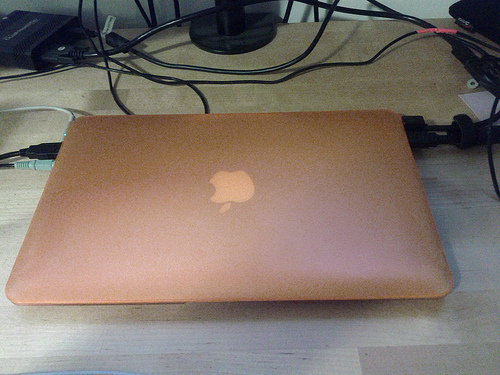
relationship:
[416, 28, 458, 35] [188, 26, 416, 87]
seal on cord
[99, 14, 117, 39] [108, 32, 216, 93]
tag on cord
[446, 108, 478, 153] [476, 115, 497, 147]
strap on cord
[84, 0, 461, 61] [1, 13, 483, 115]
cord are on desk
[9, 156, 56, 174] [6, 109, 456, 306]
plug in laptop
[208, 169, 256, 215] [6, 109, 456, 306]
logo on laptop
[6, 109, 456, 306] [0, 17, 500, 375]
laptop on desk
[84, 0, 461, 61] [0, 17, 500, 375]
cord are on desk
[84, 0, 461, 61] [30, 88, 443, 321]
cord by computer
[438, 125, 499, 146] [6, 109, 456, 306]
cord on laptop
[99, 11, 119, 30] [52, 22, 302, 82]
tag on cord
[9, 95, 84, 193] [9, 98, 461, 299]
cords inserted in laptop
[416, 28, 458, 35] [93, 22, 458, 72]
seal on cord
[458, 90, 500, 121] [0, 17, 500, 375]
paper on desk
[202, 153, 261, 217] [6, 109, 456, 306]
logo on laptop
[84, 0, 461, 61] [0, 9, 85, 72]
cord attached to box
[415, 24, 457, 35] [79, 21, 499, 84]
seal wrapped around wire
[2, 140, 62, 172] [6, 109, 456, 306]
wire plugged into laptop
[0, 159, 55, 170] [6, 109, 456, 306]
wire plugged into laptop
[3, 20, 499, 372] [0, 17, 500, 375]
cloth on desk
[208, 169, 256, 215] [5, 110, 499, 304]
logo on laptop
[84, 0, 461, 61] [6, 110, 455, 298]
cord behind lapop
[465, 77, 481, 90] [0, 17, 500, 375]
button on desk